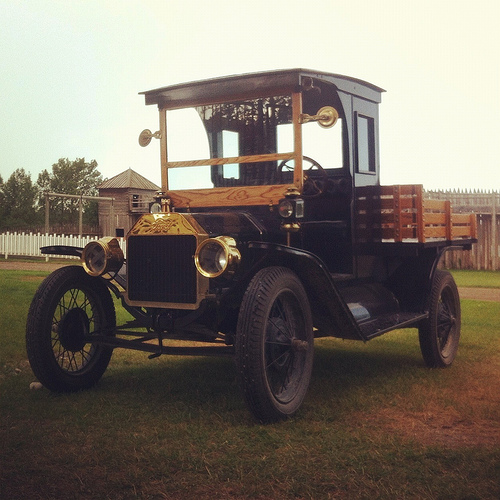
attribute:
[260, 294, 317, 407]
spokes — black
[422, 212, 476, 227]
slats — brown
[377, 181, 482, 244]
tailgate — wooden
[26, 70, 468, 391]
car — old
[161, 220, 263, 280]
headlight — brass, vintage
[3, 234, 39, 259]
fence — white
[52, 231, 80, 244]
fence — white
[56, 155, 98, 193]
leaves — green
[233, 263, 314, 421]
tire — black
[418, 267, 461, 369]
tire — black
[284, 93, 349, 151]
car mirror — brass, vintage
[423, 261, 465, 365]
tire — thin, black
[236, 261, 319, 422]
tire — thin, black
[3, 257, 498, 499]
grass — green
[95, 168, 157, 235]
building — wood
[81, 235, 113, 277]
light — shiny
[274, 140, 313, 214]
steering wheel — round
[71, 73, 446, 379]
car — old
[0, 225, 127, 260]
fence — white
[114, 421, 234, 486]
grass — patchy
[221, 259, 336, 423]
wheel — round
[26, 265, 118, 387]
tire — black, thin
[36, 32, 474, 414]
car — old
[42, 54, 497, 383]
car — old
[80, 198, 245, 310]
car front — brass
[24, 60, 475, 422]
car — old, antique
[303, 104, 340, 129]
mirror — brass, vintage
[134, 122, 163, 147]
mirror — brass, vintage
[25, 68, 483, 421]
truck — old fashioned